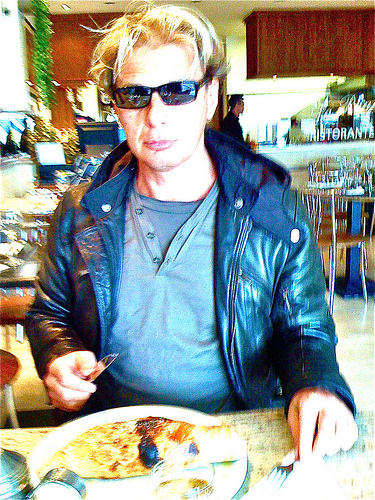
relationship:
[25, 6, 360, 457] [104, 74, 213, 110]
man has glasses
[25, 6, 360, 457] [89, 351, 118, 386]
man has knife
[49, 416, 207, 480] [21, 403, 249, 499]
egg on plate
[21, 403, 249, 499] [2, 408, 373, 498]
plate on table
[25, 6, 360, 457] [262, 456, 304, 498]
man has fork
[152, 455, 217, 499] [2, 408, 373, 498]
cup on table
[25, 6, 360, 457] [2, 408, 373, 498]
man at table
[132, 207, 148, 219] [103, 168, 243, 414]
button on shirt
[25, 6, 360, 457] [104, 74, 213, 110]
man in glasses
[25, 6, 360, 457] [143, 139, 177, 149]
man has lips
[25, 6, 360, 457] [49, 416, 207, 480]
man eating egg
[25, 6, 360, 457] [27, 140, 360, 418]
man in jacket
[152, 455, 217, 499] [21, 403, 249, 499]
cup by plate